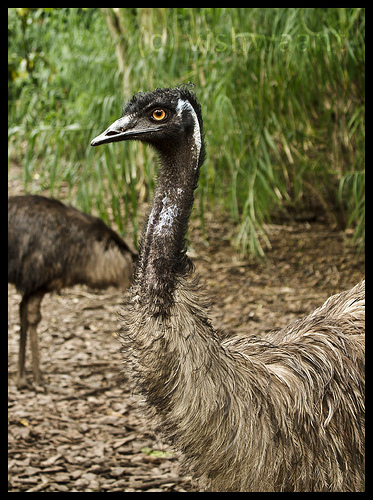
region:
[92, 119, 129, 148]
bird's beak is black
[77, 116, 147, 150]
bird's beak is black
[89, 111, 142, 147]
bird's beak is black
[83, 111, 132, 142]
bird's beak is black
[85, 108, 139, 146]
bird's beak is black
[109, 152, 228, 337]
bird's neck is long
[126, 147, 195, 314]
bird's neck is long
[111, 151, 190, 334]
bird's neck is long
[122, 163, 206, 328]
bird's neck is long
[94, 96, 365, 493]
this is a bird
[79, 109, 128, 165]
the beak of a bird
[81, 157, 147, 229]
this is a branch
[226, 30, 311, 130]
this is a branch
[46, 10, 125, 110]
this is a branch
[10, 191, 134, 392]
this is a bird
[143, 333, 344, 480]
the feathers are brown